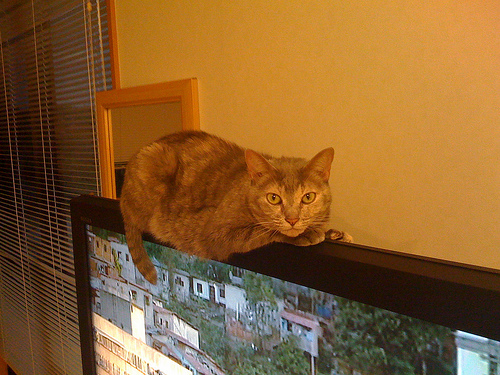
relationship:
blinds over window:
[1, 4, 115, 374] [1, 2, 112, 373]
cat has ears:
[120, 129, 352, 291] [237, 146, 336, 177]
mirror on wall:
[96, 78, 201, 210] [115, 1, 499, 265]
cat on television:
[120, 129, 352, 291] [53, 194, 498, 373]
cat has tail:
[120, 129, 352, 291] [121, 215, 161, 283]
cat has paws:
[120, 129, 352, 291] [281, 227, 353, 248]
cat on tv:
[120, 129, 352, 291] [53, 194, 498, 373]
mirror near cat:
[96, 78, 201, 210] [120, 129, 352, 291]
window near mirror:
[1, 2, 112, 373] [96, 78, 201, 210]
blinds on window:
[1, 4, 115, 374] [1, 2, 112, 373]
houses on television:
[88, 242, 327, 372] [53, 194, 498, 373]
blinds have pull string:
[1, 4, 115, 374] [78, 1, 106, 117]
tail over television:
[121, 215, 161, 283] [53, 194, 498, 373]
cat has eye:
[120, 129, 352, 291] [264, 188, 318, 205]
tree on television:
[242, 279, 455, 375] [53, 194, 498, 373]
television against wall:
[53, 194, 498, 373] [115, 1, 499, 265]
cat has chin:
[120, 129, 352, 291] [284, 230, 303, 238]